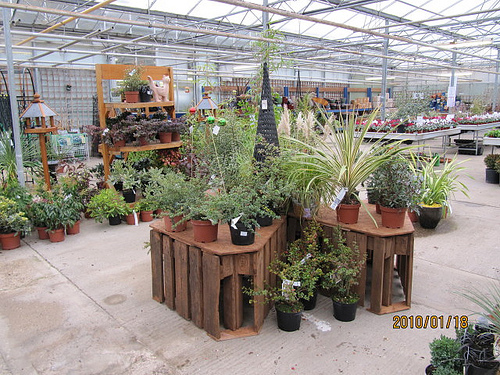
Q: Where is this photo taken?
A: Greenhouse.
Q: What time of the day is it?
A: Daytime.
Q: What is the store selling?
A: Plants.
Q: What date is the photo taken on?
A: January 18, 2010.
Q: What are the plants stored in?
A: Ceramic planters.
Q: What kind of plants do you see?
A: Flowers and house plant.